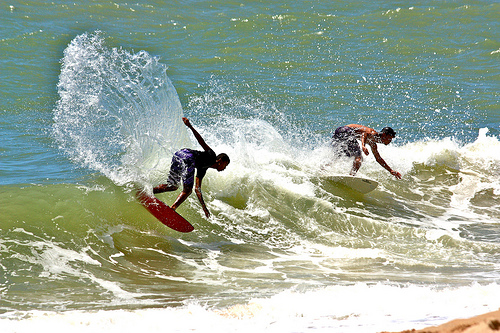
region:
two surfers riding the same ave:
[138, 80, 403, 230]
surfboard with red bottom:
[124, 177, 191, 246]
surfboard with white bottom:
[321, 169, 384, 204]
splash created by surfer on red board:
[52, 34, 181, 181]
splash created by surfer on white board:
[202, 71, 325, 167]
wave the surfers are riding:
[5, 142, 495, 275]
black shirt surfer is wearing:
[189, 132, 216, 179]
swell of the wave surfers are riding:
[3, 179, 497, 289]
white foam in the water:
[20, 185, 499, 304]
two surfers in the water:
[120, 104, 407, 239]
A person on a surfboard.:
[137, 116, 231, 233]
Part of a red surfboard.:
[174, 212, 194, 236]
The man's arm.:
[181, 114, 213, 149]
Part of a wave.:
[97, 76, 137, 135]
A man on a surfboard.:
[308, 124, 403, 191]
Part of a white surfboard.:
[358, 174, 378, 193]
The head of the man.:
[379, 127, 396, 145]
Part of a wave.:
[9, 187, 96, 237]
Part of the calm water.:
[170, 17, 213, 59]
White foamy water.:
[453, 185, 471, 205]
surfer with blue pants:
[134, 114, 229, 236]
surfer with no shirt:
[308, 122, 402, 198]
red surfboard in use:
[131, 181, 194, 234]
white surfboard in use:
[319, 172, 379, 196]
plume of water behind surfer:
[51, 29, 193, 194]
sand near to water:
[369, 304, 499, 332]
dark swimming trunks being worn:
[328, 125, 363, 160]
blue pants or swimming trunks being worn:
[165, 146, 198, 194]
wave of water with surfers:
[1, 82, 498, 302]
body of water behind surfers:
[1, 1, 498, 186]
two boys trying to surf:
[75, 59, 412, 274]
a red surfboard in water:
[115, 168, 210, 255]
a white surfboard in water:
[303, 158, 400, 214]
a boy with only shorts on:
[323, 107, 401, 178]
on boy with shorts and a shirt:
[115, 111, 244, 231]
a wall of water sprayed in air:
[51, 27, 218, 207]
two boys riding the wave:
[106, 86, 473, 239]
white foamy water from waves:
[81, 231, 456, 327]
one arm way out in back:
[164, 101, 242, 167]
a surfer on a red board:
[72, 87, 253, 271]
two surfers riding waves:
[60, 75, 465, 259]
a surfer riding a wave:
[286, 103, 426, 203]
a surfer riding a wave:
[134, 100, 239, 265]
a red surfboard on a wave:
[126, 188, 198, 240]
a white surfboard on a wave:
[318, 160, 385, 205]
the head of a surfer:
[378, 123, 400, 147]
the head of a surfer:
[211, 148, 236, 176]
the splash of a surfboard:
[16, 20, 173, 180]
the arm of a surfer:
[370, 142, 407, 180]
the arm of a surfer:
[174, 106, 211, 151]